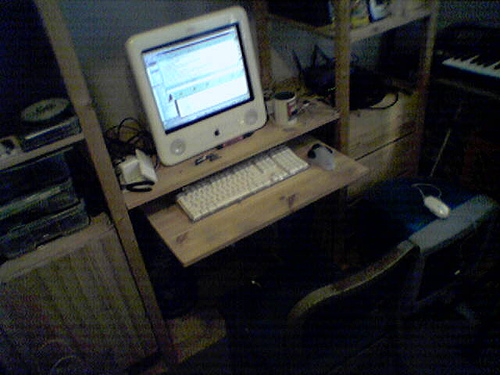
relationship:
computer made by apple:
[120, 9, 278, 167] [212, 128, 222, 141]